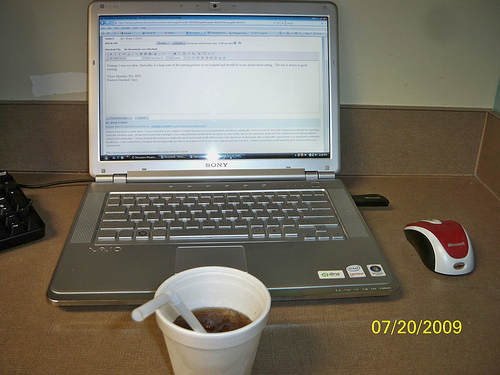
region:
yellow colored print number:
[370, 318, 381, 333]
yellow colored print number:
[380, 317, 390, 332]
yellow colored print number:
[395, 316, 405, 332]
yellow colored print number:
[406, 316, 416, 333]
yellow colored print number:
[420, 316, 432, 331]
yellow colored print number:
[430, 317, 441, 333]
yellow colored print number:
[440, 318, 453, 334]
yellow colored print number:
[451, 315, 462, 335]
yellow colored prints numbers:
[370, 316, 388, 333]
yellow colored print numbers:
[422, 318, 464, 334]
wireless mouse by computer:
[401, 215, 476, 276]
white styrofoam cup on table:
[131, 264, 267, 373]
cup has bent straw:
[124, 267, 271, 374]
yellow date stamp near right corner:
[367, 317, 461, 339]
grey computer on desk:
[47, 4, 402, 307]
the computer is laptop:
[49, 1, 398, 311]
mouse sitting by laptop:
[398, 213, 474, 278]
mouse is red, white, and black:
[404, 212, 471, 279]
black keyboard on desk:
[1, 171, 43, 258]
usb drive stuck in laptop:
[348, 191, 389, 211]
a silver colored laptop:
[52, 5, 392, 299]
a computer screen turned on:
[97, 7, 334, 165]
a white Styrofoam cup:
[142, 271, 264, 373]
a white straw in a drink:
[125, 284, 237, 350]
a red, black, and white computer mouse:
[402, 214, 478, 284]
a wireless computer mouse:
[394, 208, 486, 288]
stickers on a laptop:
[312, 257, 384, 291]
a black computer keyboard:
[0, 164, 52, 249]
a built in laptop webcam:
[207, 0, 222, 12]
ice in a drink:
[192, 305, 249, 337]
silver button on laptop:
[98, 228, 119, 244]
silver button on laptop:
[116, 228, 133, 239]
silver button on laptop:
[151, 228, 165, 240]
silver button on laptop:
[166, 227, 249, 237]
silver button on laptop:
[250, 225, 266, 238]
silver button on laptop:
[267, 224, 284, 237]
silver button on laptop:
[281, 223, 296, 240]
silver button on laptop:
[303, 227, 318, 239]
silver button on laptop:
[315, 230, 331, 242]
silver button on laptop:
[329, 229, 343, 241]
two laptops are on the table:
[7, 159, 327, 276]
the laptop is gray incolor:
[99, 197, 373, 289]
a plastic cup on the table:
[123, 281, 313, 374]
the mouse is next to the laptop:
[396, 184, 480, 295]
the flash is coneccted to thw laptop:
[352, 187, 399, 199]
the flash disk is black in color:
[355, 179, 395, 209]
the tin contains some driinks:
[152, 269, 268, 373]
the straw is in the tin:
[126, 294, 225, 344]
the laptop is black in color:
[1, 179, 41, 250]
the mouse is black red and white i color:
[413, 209, 460, 291]